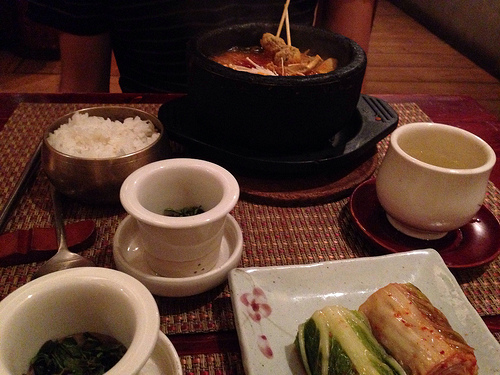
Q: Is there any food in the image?
A: Yes, there is food.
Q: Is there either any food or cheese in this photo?
A: Yes, there is food.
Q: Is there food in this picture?
A: Yes, there is food.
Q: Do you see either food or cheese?
A: Yes, there is food.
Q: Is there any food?
A: Yes, there is food.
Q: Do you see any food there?
A: Yes, there is food.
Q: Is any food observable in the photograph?
A: Yes, there is food.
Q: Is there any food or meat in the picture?
A: Yes, there is food.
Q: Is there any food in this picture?
A: Yes, there is food.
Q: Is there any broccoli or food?
A: Yes, there is food.